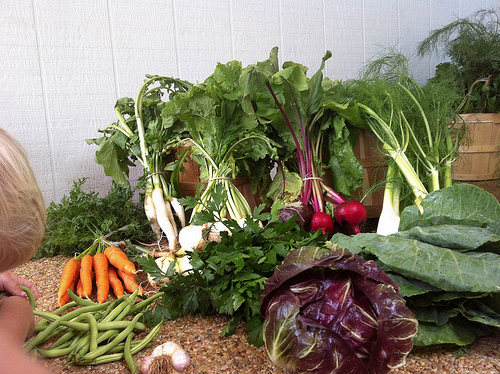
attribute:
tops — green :
[205, 56, 339, 158]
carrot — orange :
[56, 244, 148, 303]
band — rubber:
[209, 169, 273, 210]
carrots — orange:
[36, 169, 154, 329]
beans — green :
[32, 289, 155, 351]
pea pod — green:
[77, 306, 101, 353]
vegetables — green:
[130, 103, 381, 317]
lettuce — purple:
[244, 216, 432, 371]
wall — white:
[0, 0, 497, 206]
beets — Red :
[235, 57, 382, 228]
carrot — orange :
[43, 230, 138, 313]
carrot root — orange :
[98, 233, 140, 278]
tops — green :
[174, 70, 266, 175]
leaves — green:
[226, 74, 301, 136]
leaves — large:
[336, 184, 496, 348]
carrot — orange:
[55, 254, 76, 313]